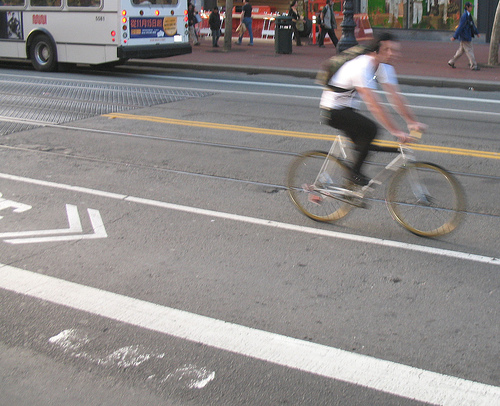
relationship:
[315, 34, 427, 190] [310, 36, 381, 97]
guy with backpack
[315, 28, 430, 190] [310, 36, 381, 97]
guy with backpack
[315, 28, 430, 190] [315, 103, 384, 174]
guy wearing black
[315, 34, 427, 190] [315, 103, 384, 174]
guy wearing black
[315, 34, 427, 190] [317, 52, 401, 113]
guy in shirt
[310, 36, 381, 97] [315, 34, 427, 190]
backpack on guy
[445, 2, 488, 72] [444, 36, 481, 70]
person in pants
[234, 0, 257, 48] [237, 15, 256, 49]
man in jeans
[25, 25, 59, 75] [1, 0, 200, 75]
tire on bus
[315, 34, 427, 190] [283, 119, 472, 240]
guy riding bicycle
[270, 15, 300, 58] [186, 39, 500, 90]
can on sidewalk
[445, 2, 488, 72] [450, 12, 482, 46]
person in jacket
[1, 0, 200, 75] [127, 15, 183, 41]
bus has ad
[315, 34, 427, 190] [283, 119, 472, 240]
guy on bike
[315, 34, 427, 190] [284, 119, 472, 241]
guy rides bicycle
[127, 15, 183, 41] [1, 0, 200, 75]
advertisment on bus